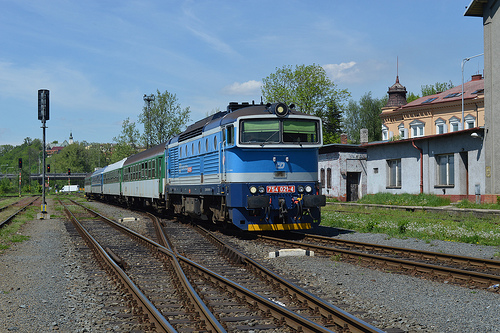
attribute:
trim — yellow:
[246, 220, 316, 235]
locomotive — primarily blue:
[160, 81, 317, 271]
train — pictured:
[65, 100, 322, 235]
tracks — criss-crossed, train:
[57, 192, 499, 332]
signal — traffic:
[34, 85, 52, 125]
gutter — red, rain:
[407, 137, 429, 195]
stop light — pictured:
[14, 154, 26, 196]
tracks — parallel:
[0, 185, 498, 332]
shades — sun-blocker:
[248, 117, 310, 134]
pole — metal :
[35, 124, 52, 221]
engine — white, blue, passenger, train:
[163, 101, 330, 236]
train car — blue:
[83, 98, 324, 233]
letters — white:
[262, 180, 307, 197]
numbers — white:
[266, 179, 309, 197]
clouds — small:
[228, 74, 265, 98]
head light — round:
[265, 95, 300, 125]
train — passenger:
[58, 87, 342, 271]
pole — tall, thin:
[35, 118, 52, 204]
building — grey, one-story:
[346, 123, 498, 211]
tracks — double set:
[72, 204, 346, 331]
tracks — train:
[34, 207, 474, 330]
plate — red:
[260, 174, 317, 194]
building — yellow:
[364, 45, 498, 128]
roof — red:
[388, 77, 489, 112]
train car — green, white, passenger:
[118, 143, 168, 206]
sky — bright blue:
[2, 1, 482, 142]